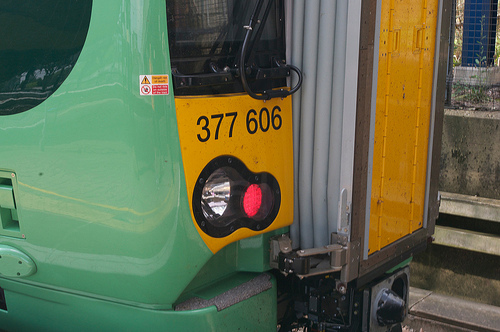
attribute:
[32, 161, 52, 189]
speck — black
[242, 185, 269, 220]
light — red, round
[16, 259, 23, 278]
bolts — small, black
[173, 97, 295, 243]
number panel — yellow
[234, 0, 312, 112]
hose — black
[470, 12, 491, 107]
plant — small, green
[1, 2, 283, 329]
panel — green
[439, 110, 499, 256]
concrete wall — grey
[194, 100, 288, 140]
377 606 — black, number